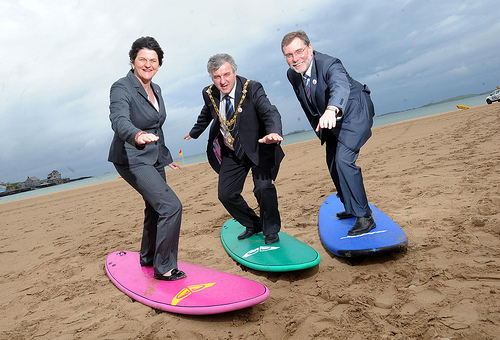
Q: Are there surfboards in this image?
A: Yes, there is a surfboard.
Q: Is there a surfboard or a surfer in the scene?
A: Yes, there is a surfboard.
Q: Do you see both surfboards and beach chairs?
A: No, there is a surfboard but no beach chairs.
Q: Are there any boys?
A: No, there are no boys.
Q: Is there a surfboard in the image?
A: Yes, there is a surfboard.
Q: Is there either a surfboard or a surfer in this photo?
A: Yes, there is a surfboard.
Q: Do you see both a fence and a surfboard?
A: No, there is a surfboard but no fences.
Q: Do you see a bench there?
A: No, there are no benches.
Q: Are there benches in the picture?
A: No, there are no benches.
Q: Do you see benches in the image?
A: No, there are no benches.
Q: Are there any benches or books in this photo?
A: No, there are no benches or books.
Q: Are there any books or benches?
A: No, there are no benches or books.